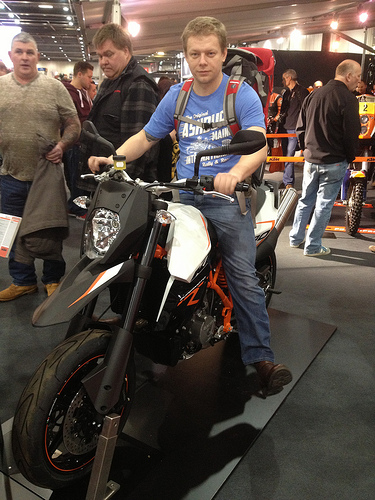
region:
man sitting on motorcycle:
[86, 16, 293, 397]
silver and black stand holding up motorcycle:
[0, 304, 338, 499]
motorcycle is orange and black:
[11, 119, 299, 489]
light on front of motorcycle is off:
[91, 208, 119, 253]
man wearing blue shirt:
[143, 73, 265, 195]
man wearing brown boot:
[253, 359, 292, 396]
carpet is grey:
[0, 161, 374, 499]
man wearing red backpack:
[173, 46, 274, 136]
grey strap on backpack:
[173, 113, 236, 130]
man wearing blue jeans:
[170, 192, 275, 365]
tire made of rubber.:
[28, 376, 56, 419]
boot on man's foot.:
[265, 364, 292, 395]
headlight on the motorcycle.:
[95, 213, 114, 244]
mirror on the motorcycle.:
[233, 135, 263, 153]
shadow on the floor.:
[223, 419, 255, 460]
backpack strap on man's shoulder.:
[226, 77, 241, 126]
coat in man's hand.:
[41, 170, 65, 226]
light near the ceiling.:
[355, 10, 368, 25]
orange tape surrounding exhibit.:
[264, 155, 297, 167]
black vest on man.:
[107, 91, 123, 114]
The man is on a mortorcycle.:
[142, 53, 280, 320]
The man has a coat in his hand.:
[37, 134, 73, 260]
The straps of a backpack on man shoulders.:
[174, 74, 242, 146]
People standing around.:
[262, 51, 353, 218]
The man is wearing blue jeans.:
[296, 154, 351, 250]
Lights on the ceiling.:
[274, 23, 374, 39]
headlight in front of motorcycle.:
[83, 197, 125, 248]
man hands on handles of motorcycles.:
[170, 152, 263, 208]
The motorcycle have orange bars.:
[179, 255, 241, 346]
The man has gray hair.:
[10, 25, 42, 43]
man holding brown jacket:
[3, 32, 74, 305]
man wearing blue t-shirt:
[88, 10, 292, 393]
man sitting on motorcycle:
[8, 13, 359, 487]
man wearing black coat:
[285, 52, 365, 268]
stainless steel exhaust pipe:
[265, 186, 306, 233]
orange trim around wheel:
[36, 350, 142, 473]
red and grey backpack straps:
[165, 65, 262, 147]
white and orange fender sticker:
[65, 263, 135, 314]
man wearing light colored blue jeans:
[294, 51, 367, 266]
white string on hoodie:
[71, 84, 86, 110]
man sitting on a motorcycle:
[9, 15, 298, 491]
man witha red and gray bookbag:
[171, 14, 283, 138]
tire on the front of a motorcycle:
[9, 325, 139, 491]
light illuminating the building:
[285, 7, 370, 39]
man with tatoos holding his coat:
[0, 30, 77, 264]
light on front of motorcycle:
[81, 204, 118, 255]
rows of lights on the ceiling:
[2, 1, 86, 63]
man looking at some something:
[289, 58, 364, 257]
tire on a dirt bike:
[343, 176, 368, 236]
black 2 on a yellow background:
[359, 101, 373, 113]